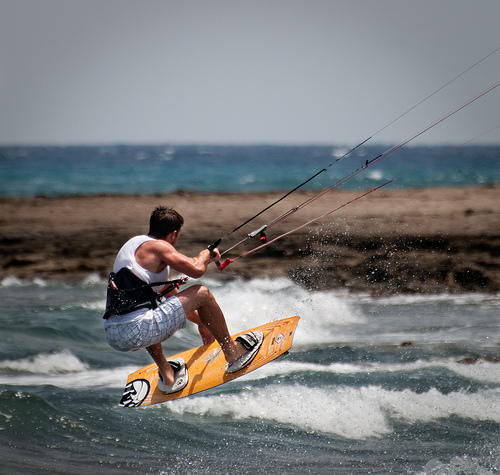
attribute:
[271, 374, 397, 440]
water — rough, sparkling, glistening, splashing, shiny, ramunctious, zealous, choppy, spraying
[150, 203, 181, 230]
hair — dark, short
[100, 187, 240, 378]
man — parasailing, skiing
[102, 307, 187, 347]
shorts — white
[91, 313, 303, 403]
board — orange, yellow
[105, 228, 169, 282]
shirt — white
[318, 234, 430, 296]
shore — rocky, brown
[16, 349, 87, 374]
wave — white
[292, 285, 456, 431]
waves — crashing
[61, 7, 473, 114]
sky — hazy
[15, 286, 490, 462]
ocean — calm, blue